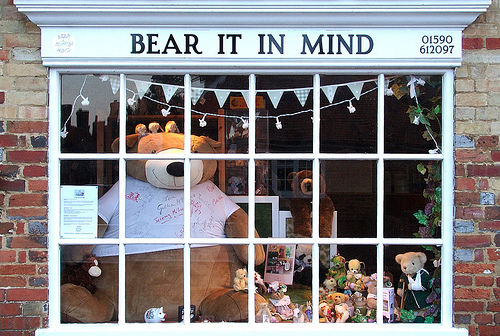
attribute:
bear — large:
[49, 111, 279, 324]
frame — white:
[44, 67, 454, 324]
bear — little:
[51, 131, 267, 328]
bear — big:
[228, 262, 255, 295]